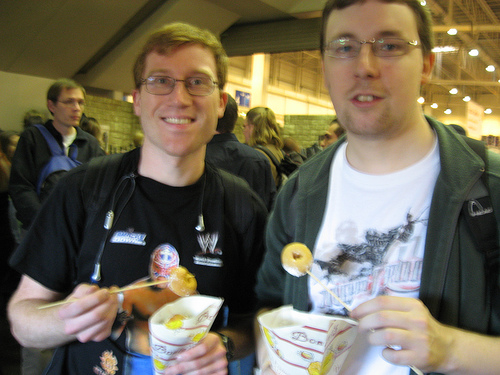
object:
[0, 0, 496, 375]
scene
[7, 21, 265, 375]
boys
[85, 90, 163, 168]
wall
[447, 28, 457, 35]
light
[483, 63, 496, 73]
light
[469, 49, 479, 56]
light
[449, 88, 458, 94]
light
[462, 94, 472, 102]
light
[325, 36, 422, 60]
eyeglasses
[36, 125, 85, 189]
backpack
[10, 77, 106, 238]
man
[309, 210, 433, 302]
design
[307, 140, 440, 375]
shirt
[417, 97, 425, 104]
light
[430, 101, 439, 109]
light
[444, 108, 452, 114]
light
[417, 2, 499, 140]
ceiling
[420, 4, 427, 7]
light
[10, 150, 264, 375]
shirt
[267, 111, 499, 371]
jacket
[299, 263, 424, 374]
stick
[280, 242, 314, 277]
donut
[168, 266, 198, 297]
donut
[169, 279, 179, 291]
sugar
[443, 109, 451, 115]
lights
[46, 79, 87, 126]
head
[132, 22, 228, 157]
head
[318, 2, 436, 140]
head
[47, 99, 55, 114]
ear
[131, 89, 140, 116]
ear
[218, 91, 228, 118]
ear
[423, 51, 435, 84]
ear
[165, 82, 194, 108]
nose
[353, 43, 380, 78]
nose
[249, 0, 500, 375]
man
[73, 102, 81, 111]
nose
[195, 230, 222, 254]
w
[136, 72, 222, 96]
eyeglass